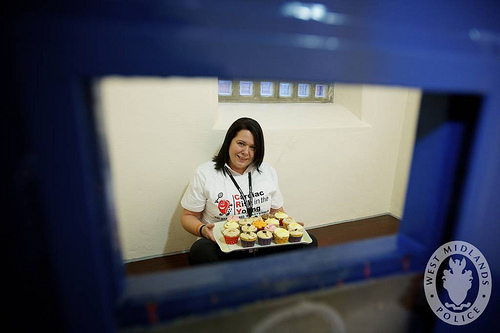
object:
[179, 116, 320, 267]
woman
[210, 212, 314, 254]
tray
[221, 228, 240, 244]
cupcake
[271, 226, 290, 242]
cupcake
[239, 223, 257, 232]
cupcake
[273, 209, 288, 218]
cupcake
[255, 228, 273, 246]
cupcake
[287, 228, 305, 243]
cupcake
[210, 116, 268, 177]
hair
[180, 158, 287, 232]
t-shirt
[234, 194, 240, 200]
letter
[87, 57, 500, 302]
window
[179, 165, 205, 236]
arm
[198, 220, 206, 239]
wrist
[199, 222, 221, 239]
band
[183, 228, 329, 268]
pants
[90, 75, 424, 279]
room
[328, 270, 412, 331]
door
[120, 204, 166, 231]
glass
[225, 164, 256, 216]
lanyard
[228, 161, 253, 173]
neck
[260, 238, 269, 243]
liner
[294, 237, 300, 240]
liner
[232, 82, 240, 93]
bar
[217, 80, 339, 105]
window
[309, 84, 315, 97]
bar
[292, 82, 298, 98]
bar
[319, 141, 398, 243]
jail cell